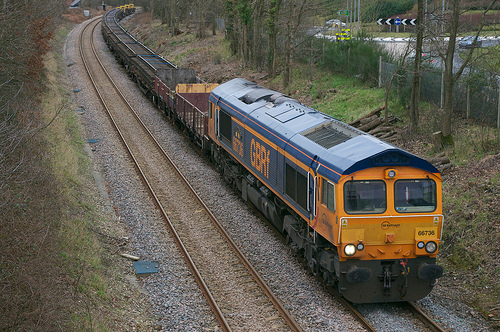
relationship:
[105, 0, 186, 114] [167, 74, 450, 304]
train cars are pulled by engine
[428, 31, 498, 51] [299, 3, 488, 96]
car on road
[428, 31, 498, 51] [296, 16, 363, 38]
car on train tracks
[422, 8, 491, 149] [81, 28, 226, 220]
tree side tracks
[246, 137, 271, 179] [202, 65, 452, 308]
logo painted on train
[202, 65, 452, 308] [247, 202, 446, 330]
train riding on track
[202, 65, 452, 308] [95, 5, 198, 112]
train front car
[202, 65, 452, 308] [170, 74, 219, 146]
train pulls cart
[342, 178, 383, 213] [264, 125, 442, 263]
window on front of train